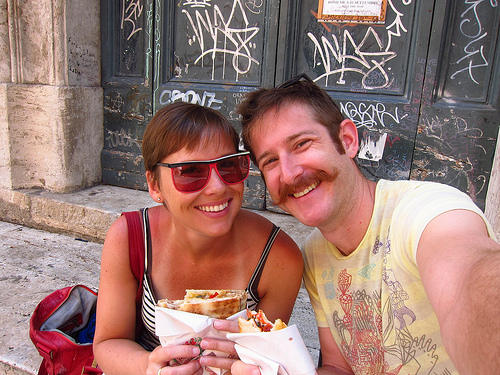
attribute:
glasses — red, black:
[161, 164, 252, 188]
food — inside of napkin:
[156, 283, 285, 333]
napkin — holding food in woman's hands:
[155, 305, 251, 340]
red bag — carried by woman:
[26, 280, 105, 372]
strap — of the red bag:
[117, 210, 153, 281]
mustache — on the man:
[265, 169, 341, 207]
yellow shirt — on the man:
[287, 177, 481, 360]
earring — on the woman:
[156, 192, 165, 205]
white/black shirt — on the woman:
[131, 202, 285, 343]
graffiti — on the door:
[92, 0, 484, 117]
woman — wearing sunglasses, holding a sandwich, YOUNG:
[92, 98, 306, 368]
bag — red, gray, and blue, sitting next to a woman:
[25, 281, 105, 369]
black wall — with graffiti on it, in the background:
[101, 0, 481, 91]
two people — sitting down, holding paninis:
[88, 74, 480, 373]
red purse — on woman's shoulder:
[28, 205, 139, 372]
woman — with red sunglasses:
[151, 150, 254, 196]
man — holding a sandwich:
[241, 74, 484, 345]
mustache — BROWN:
[271, 169, 340, 208]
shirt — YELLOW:
[300, 175, 463, 362]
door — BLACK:
[163, 11, 429, 98]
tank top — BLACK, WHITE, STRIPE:
[137, 218, 284, 343]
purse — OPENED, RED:
[21, 280, 106, 367]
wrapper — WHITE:
[170, 285, 238, 308]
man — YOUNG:
[249, 63, 455, 365]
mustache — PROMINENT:
[274, 166, 339, 206]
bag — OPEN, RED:
[26, 283, 119, 368]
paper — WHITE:
[154, 331, 301, 363]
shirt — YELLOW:
[297, 179, 479, 368]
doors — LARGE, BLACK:
[156, 9, 423, 88]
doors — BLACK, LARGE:
[153, 9, 428, 101]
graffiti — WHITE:
[160, 10, 416, 91]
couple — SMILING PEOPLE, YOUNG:
[84, 70, 453, 360]